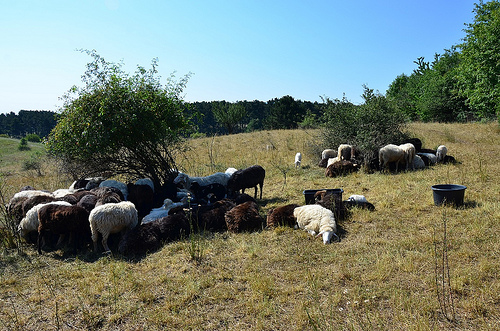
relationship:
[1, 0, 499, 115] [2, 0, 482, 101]
clouds in sky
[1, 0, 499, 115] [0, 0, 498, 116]
clouds in sky